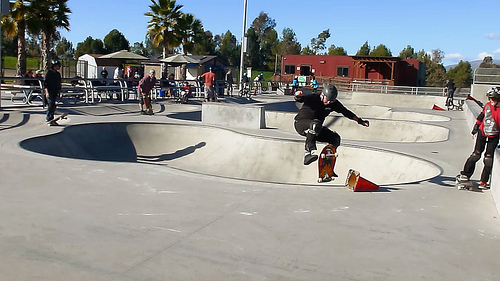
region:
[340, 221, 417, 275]
part of the floor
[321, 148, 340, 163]
wheels of a skateboard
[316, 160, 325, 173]
edge of a skateboard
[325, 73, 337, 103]
part of a helmet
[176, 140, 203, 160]
part of a shaow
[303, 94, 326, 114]
part of a black top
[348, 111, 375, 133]
part of a glove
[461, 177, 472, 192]
part of a skateboard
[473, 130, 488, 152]
part of a trouser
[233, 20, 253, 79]
part of a post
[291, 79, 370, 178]
skater in the air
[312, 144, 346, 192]
skateboard with white wheels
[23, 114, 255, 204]
bowl for skaters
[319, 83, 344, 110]
helmet on skater's head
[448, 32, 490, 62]
white clouds in the sky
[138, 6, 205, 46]
palm tree in the background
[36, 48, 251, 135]
many different skaters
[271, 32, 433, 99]
red and brown building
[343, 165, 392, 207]
orange cone on its side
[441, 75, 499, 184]
skater watching other skater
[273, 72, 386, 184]
A skateboarder with black attire on and a black helmet.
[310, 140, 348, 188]
An orange skateboard.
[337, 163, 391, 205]
An orange cone on its side.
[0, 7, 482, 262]
A skateboard park.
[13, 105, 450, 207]
A skateboard track.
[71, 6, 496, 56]
A clear day.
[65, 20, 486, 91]
A row of trees in the background.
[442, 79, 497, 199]
A skateboarder with red attire.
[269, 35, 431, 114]
A red building in the background.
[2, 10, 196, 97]
A palm trees.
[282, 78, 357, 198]
a man skateboarding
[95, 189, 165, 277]
the gravel of the skate park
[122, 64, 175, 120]
a man taking a break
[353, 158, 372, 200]
an orange cone fallen down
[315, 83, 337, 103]
the boarders helmet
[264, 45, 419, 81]
a red building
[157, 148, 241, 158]
a shadow casted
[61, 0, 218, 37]
a palm tree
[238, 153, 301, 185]
a skate ram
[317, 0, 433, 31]
nice blue sky on a cleat day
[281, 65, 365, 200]
man performing skateboard trick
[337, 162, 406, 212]
orange traffic cone on its side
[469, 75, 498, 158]
young man wearing red shirt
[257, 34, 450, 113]
red building next to a skate park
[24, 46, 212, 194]
man casting shadow into empty pool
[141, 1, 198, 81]
tall palm tree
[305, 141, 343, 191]
skateboard with red bottom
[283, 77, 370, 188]
skateboarder wearing a helmet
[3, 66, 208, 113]
white and blue metal benches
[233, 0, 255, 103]
tall light pole